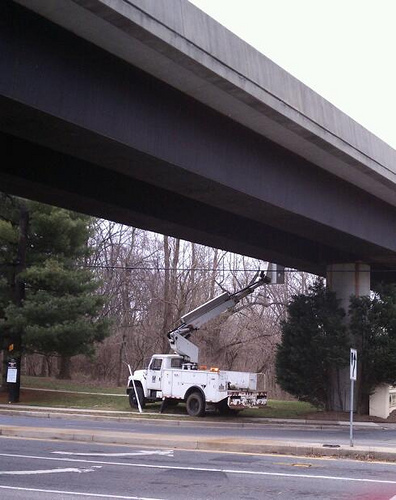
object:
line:
[101, 454, 324, 495]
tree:
[272, 276, 355, 411]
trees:
[347, 287, 395, 415]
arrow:
[0, 463, 103, 476]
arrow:
[48, 447, 175, 461]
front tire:
[128, 383, 146, 409]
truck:
[126, 352, 268, 417]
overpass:
[0, 0, 395, 416]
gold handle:
[18, 222, 114, 379]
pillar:
[321, 251, 370, 413]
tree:
[17, 210, 112, 387]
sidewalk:
[306, 414, 334, 425]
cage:
[275, 259, 285, 285]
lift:
[165, 276, 265, 363]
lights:
[276, 270, 283, 277]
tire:
[186, 389, 205, 417]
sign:
[348, 346, 358, 381]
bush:
[273, 271, 395, 416]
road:
[0, 400, 395, 497]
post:
[349, 377, 354, 448]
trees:
[89, 214, 151, 386]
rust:
[226, 390, 267, 411]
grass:
[26, 386, 128, 404]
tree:
[0, 196, 115, 401]